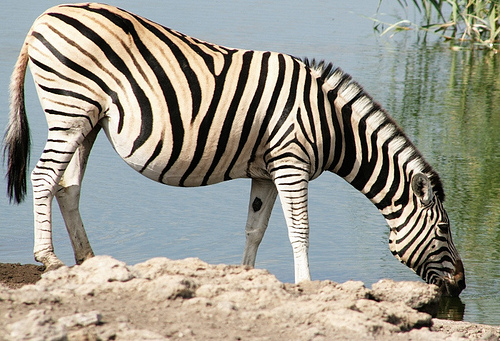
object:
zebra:
[0, 1, 466, 298]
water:
[89, 187, 240, 255]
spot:
[251, 196, 263, 212]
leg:
[241, 178, 276, 268]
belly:
[99, 76, 269, 188]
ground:
[0, 254, 500, 341]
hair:
[0, 120, 31, 206]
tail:
[0, 27, 31, 207]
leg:
[267, 159, 312, 285]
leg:
[29, 103, 99, 264]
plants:
[368, 0, 498, 53]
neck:
[317, 73, 436, 221]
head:
[386, 172, 467, 297]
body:
[26, 2, 335, 187]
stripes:
[278, 178, 309, 185]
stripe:
[46, 11, 153, 159]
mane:
[302, 56, 445, 202]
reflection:
[384, 40, 500, 259]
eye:
[437, 223, 450, 234]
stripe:
[326, 88, 342, 172]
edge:
[79, 254, 122, 271]